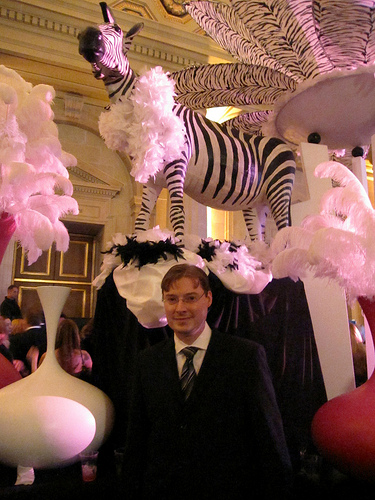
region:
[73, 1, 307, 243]
A large zebra statue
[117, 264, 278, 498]
a man in a three piece suit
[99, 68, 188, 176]
a white feather boa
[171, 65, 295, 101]
black and white striped feathers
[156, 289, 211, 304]
a pair of spectacles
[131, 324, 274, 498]
a black three piece suit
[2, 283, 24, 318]
a man wearing a black sweater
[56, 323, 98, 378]
a woman with long brown hair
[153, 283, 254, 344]
man is wearing eyeglasses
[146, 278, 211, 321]
man is wearing eyeglasses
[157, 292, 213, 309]
man is wearing eyeglasses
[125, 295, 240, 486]
the suit is black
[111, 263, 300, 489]
man in a suit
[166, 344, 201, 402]
tie on a man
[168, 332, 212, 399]
white shirt on man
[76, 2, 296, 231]
zebra float above man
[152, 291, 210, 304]
glasses on man's face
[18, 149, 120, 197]
triangular structure above door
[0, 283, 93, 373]
people at an event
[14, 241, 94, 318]
doorway to the room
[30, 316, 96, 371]
woman with thin dress straps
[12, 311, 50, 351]
man in crowd in suit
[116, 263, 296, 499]
a guy in a suit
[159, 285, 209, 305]
a guy wearing glasses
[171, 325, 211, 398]
a white shirt and tie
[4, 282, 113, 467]
a large white vase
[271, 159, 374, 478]
feathers in a red vase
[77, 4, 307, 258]
a zebra with white feathers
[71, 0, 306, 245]
white feathers on a zebra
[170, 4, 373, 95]
black and white plumes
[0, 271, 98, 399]
people behind the vase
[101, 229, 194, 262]
black and white feathers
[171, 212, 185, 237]
Black and white stripes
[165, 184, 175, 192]
Black and white stripes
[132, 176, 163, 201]
Black and white stripes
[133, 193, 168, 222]
Black and white stripes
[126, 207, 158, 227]
Black and white stripes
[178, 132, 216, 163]
Black and white stripes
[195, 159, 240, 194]
Black and white stripes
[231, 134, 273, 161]
Black and white stripes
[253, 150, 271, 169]
Black and white stripes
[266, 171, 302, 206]
Black and white stripes